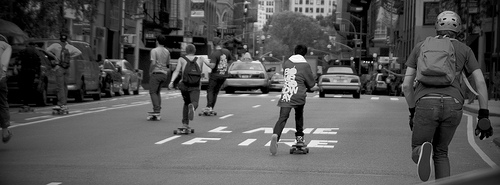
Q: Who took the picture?
A: A friend.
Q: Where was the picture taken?
A: The street.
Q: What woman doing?
A: Rollerblading.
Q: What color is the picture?
A: Black and white.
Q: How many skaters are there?
A: Five.